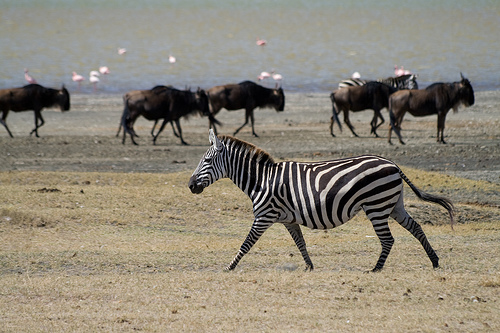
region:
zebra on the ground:
[147, 102, 450, 267]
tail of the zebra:
[425, 160, 468, 226]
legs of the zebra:
[199, 208, 437, 300]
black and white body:
[260, 159, 353, 227]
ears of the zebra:
[196, 113, 242, 161]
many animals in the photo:
[5, 45, 488, 308]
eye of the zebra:
[194, 150, 224, 173]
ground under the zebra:
[126, 234, 223, 319]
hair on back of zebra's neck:
[226, 128, 286, 166]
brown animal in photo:
[0, 75, 87, 146]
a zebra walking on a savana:
[177, 121, 464, 277]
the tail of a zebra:
[392, 159, 465, 231]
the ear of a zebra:
[205, 120, 225, 150]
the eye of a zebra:
[200, 151, 215, 166]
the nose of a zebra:
[185, 173, 202, 198]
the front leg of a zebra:
[220, 211, 274, 275]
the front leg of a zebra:
[278, 218, 315, 275]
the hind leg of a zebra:
[364, 189, 396, 274]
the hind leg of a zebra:
[395, 201, 442, 273]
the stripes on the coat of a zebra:
[272, 168, 353, 215]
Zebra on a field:
[188, 126, 453, 276]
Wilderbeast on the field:
[385, 73, 477, 151]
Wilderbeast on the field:
[202, 81, 289, 137]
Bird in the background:
[243, 30, 274, 61]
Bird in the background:
[157, 45, 182, 74]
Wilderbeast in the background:
[1, 81, 73, 140]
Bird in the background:
[251, 65, 268, 85]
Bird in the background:
[267, 66, 287, 91]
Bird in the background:
[107, 40, 135, 69]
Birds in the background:
[68, 52, 120, 99]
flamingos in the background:
[110, 38, 135, 70]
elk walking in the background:
[0, 86, 82, 141]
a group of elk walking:
[2, 62, 498, 161]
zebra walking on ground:
[173, 118, 460, 290]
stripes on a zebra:
[271, 161, 380, 207]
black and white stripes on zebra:
[267, 170, 350, 217]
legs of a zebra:
[368, 209, 405, 275]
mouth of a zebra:
[172, 167, 218, 195]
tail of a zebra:
[386, 164, 465, 211]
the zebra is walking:
[155, 106, 457, 318]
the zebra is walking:
[159, 119, 469, 293]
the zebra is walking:
[163, 124, 485, 292]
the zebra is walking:
[161, 112, 458, 304]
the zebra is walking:
[160, 109, 474, 294]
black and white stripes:
[162, 124, 464, 289]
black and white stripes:
[155, 113, 467, 294]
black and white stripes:
[166, 117, 458, 308]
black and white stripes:
[175, 117, 484, 289]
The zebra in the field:
[187, 123, 459, 273]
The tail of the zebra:
[397, 166, 423, 196]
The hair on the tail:
[418, 191, 456, 226]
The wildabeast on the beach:
[384, 70, 476, 147]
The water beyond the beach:
[1, 0, 498, 93]